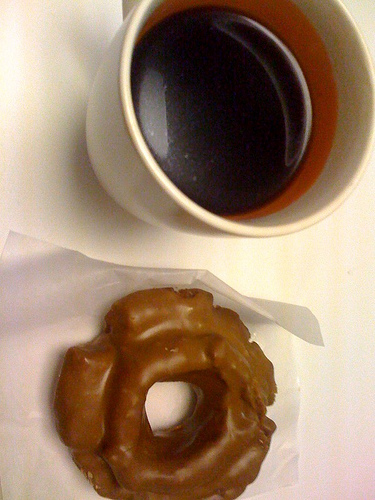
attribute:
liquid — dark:
[138, 10, 315, 206]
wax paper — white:
[3, 225, 312, 499]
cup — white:
[93, 2, 370, 255]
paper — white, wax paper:
[1, 228, 324, 498]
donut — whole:
[52, 286, 277, 498]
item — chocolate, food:
[39, 261, 284, 484]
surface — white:
[10, 201, 362, 494]